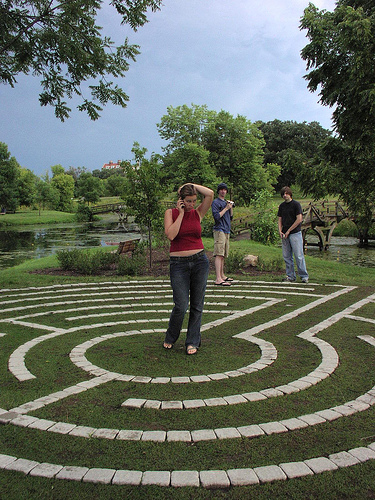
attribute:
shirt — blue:
[212, 197, 237, 232]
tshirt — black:
[275, 204, 304, 235]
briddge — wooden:
[107, 235, 141, 257]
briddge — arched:
[228, 205, 319, 236]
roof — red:
[102, 158, 126, 165]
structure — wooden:
[271, 188, 353, 250]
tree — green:
[311, 20, 372, 195]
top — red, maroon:
[166, 212, 210, 252]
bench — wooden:
[261, 200, 344, 244]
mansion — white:
[103, 155, 135, 171]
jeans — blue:
[279, 239, 315, 281]